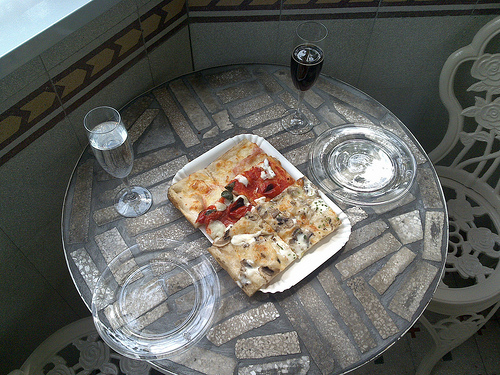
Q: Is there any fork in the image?
A: No, there are no forks.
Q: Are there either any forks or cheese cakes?
A: No, there are no forks or cheese cakes.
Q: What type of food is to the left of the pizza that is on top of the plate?
A: The food is a mushroom.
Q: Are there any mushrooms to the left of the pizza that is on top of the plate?
A: Yes, there is a mushroom to the left of the pizza.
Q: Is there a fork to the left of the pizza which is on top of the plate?
A: No, there is a mushroom to the left of the pizza.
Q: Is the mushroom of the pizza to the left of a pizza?
A: Yes, the mushroom is to the left of a pizza.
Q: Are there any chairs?
A: Yes, there is a chair.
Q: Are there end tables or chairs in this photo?
A: Yes, there is a chair.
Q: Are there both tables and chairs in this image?
A: Yes, there are both a chair and a table.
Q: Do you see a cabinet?
A: No, there are no cabinets.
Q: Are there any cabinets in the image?
A: No, there are no cabinets.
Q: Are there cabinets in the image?
A: No, there are no cabinets.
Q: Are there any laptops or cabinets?
A: No, there are no cabinets or laptops.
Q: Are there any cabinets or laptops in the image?
A: No, there are no cabinets or laptops.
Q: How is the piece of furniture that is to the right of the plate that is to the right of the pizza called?
A: The piece of furniture is a chair.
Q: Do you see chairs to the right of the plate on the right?
A: Yes, there is a chair to the right of the plate.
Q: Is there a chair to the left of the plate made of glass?
A: No, the chair is to the right of the plate.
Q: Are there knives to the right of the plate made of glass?
A: No, there is a chair to the right of the plate.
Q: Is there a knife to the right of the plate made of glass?
A: No, there is a chair to the right of the plate.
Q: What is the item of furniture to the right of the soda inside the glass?
A: The piece of furniture is a chair.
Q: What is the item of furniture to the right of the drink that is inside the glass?
A: The piece of furniture is a chair.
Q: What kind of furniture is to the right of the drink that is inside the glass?
A: The piece of furniture is a chair.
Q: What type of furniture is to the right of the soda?
A: The piece of furniture is a chair.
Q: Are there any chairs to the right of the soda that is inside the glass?
A: Yes, there is a chair to the right of the soda.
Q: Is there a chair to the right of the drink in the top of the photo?
A: Yes, there is a chair to the right of the soda.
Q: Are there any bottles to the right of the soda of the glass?
A: No, there is a chair to the right of the soda.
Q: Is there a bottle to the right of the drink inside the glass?
A: No, there is a chair to the right of the soda.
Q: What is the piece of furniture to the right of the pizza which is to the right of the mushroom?
A: The piece of furniture is a chair.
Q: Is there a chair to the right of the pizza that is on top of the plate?
A: Yes, there is a chair to the right of the pizza.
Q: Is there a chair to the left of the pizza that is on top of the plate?
A: No, the chair is to the right of the pizza.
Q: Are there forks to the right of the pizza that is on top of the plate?
A: No, there is a chair to the right of the pizza.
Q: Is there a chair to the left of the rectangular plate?
A: No, the chair is to the right of the plate.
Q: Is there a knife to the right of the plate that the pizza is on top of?
A: No, there is a chair to the right of the plate.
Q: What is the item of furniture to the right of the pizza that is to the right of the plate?
A: The piece of furniture is a chair.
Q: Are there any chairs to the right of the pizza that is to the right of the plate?
A: Yes, there is a chair to the right of the pizza.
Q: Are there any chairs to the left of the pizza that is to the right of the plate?
A: No, the chair is to the right of the pizza.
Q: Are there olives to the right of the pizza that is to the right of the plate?
A: No, there is a chair to the right of the pizza.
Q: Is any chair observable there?
A: Yes, there is a chair.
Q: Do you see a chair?
A: Yes, there is a chair.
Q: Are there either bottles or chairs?
A: Yes, there is a chair.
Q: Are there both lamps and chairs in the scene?
A: No, there is a chair but no lamps.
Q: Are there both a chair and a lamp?
A: No, there is a chair but no lamps.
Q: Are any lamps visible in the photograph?
A: No, there are no lamps.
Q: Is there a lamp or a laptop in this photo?
A: No, there are no lamps or laptops.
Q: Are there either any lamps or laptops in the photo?
A: No, there are no lamps or laptops.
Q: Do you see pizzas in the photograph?
A: Yes, there is a pizza.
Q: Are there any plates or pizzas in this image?
A: Yes, there is a pizza.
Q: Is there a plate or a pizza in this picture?
A: Yes, there is a pizza.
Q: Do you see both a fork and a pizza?
A: No, there is a pizza but no forks.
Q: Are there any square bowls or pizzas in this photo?
A: Yes, there is a square pizza.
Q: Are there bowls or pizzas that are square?
A: Yes, the pizza is square.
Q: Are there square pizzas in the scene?
A: Yes, there is a square pizza.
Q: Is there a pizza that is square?
A: Yes, there is a pizza that is square.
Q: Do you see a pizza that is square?
A: Yes, there is a pizza that is square.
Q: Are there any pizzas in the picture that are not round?
A: Yes, there is a square pizza.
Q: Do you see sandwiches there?
A: No, there are no sandwiches.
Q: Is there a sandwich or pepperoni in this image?
A: No, there are no sandwiches or pepperoni.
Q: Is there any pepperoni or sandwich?
A: No, there are no sandwiches or pepperoni.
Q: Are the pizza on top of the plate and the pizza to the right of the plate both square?
A: Yes, both the pizza and the pizza are square.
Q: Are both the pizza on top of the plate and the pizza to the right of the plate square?
A: Yes, both the pizza and the pizza are square.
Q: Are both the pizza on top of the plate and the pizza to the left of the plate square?
A: Yes, both the pizza and the pizza are square.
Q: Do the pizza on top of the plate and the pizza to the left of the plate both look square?
A: Yes, both the pizza and the pizza are square.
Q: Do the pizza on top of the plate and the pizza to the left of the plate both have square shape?
A: Yes, both the pizza and the pizza are square.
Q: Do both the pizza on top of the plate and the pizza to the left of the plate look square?
A: Yes, both the pizza and the pizza are square.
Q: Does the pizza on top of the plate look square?
A: Yes, the pizza is square.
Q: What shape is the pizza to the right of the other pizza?
A: The pizza is square.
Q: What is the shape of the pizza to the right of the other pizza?
A: The pizza is square.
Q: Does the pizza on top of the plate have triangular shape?
A: No, the pizza is square.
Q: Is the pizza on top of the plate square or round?
A: The pizza is square.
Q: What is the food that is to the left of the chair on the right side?
A: The food is a pizza.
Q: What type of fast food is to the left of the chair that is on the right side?
A: The food is a pizza.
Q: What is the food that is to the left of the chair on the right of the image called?
A: The food is a pizza.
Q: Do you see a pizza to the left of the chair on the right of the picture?
A: Yes, there is a pizza to the left of the chair.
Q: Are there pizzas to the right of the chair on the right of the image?
A: No, the pizza is to the left of the chair.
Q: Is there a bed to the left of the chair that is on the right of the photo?
A: No, there is a pizza to the left of the chair.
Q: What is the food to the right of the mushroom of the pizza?
A: The food is a pizza.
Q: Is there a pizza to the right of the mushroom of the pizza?
A: Yes, there is a pizza to the right of the mushroom.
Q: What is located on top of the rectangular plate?
A: The pizza is on top of the plate.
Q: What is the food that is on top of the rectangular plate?
A: The food is a pizza.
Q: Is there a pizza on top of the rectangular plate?
A: Yes, there is a pizza on top of the plate.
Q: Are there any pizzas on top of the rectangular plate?
A: Yes, there is a pizza on top of the plate.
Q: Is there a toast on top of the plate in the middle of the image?
A: No, there is a pizza on top of the plate.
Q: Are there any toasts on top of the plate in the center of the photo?
A: No, there is a pizza on top of the plate.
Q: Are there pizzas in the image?
A: Yes, there is a pizza.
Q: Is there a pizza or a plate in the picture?
A: Yes, there is a pizza.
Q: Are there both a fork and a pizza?
A: No, there is a pizza but no forks.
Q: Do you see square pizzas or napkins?
A: Yes, there is a square pizza.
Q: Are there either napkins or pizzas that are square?
A: Yes, the pizza is square.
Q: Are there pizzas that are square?
A: Yes, there is a pizza that is square.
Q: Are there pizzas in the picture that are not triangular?
A: Yes, there is a square pizza.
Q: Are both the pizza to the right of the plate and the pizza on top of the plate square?
A: Yes, both the pizza and the pizza are square.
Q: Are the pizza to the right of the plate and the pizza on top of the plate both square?
A: Yes, both the pizza and the pizza are square.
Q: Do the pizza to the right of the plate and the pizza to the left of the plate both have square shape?
A: Yes, both the pizza and the pizza are square.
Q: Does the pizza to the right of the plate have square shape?
A: Yes, the pizza is square.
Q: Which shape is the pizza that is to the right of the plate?
A: The pizza is square.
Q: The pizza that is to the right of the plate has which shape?
A: The pizza is square.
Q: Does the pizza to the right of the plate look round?
A: No, the pizza is square.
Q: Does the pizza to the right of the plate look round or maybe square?
A: The pizza is square.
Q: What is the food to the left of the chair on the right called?
A: The food is a pizza.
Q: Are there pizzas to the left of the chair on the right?
A: Yes, there is a pizza to the left of the chair.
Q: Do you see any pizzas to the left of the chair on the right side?
A: Yes, there is a pizza to the left of the chair.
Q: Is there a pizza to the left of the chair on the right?
A: Yes, there is a pizza to the left of the chair.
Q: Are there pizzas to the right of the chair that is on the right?
A: No, the pizza is to the left of the chair.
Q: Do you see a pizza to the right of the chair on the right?
A: No, the pizza is to the left of the chair.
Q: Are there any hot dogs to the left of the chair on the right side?
A: No, there is a pizza to the left of the chair.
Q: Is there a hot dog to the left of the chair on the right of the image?
A: No, there is a pizza to the left of the chair.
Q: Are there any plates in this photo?
A: Yes, there is a plate.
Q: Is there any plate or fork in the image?
A: Yes, there is a plate.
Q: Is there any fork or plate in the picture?
A: Yes, there is a plate.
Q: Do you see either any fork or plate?
A: Yes, there is a plate.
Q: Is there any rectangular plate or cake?
A: Yes, there is a rectangular plate.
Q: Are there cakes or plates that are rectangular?
A: Yes, the plate is rectangular.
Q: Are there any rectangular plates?
A: Yes, there is a rectangular plate.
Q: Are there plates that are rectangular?
A: Yes, there is a plate that is rectangular.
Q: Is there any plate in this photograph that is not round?
A: Yes, there is a rectangular plate.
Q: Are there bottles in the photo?
A: No, there are no bottles.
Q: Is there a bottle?
A: No, there are no bottles.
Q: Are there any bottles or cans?
A: No, there are no bottles or cans.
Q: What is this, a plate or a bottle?
A: This is a plate.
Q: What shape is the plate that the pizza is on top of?
A: The plate is rectangular.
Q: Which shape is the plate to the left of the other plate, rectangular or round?
A: The plate is rectangular.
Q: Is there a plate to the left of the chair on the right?
A: Yes, there is a plate to the left of the chair.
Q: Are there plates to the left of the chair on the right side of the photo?
A: Yes, there is a plate to the left of the chair.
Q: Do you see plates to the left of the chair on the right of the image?
A: Yes, there is a plate to the left of the chair.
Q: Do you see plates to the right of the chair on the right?
A: No, the plate is to the left of the chair.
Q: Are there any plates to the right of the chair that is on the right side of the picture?
A: No, the plate is to the left of the chair.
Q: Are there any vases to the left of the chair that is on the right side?
A: No, there is a plate to the left of the chair.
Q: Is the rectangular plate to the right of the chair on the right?
A: No, the plate is to the left of the chair.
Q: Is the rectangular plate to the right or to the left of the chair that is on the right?
A: The plate is to the left of the chair.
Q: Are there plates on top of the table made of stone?
A: Yes, there is a plate on top of the table.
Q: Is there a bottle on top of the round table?
A: No, there is a plate on top of the table.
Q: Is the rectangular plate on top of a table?
A: Yes, the plate is on top of a table.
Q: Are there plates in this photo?
A: Yes, there is a plate.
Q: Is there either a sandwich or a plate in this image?
A: Yes, there is a plate.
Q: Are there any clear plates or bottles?
A: Yes, there is a clear plate.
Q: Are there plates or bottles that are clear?
A: Yes, the plate is clear.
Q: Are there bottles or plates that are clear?
A: Yes, the plate is clear.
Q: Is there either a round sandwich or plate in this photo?
A: Yes, there is a round plate.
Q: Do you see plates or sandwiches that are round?
A: Yes, the plate is round.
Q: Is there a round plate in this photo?
A: Yes, there is a round plate.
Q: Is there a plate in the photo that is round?
A: Yes, there is a plate that is round.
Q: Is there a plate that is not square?
A: Yes, there is a round plate.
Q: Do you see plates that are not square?
A: Yes, there is a round plate.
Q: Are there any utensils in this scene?
A: No, there are no utensils.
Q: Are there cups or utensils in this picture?
A: No, there are no utensils or cups.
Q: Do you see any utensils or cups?
A: No, there are no utensils or cups.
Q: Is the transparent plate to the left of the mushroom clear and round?
A: Yes, the plate is clear and round.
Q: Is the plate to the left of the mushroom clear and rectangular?
A: No, the plate is clear but round.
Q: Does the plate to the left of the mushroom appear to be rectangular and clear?
A: No, the plate is clear but round.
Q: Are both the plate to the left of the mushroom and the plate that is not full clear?
A: Yes, both the plate and the plate are clear.